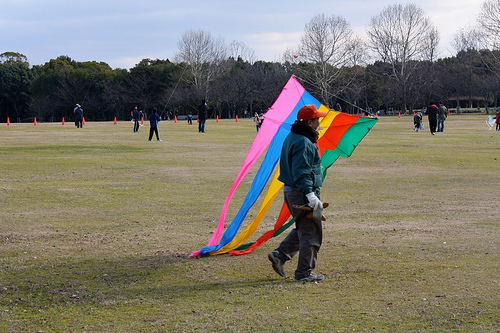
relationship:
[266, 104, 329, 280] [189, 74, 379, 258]
man with kite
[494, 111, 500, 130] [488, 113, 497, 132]
person with kite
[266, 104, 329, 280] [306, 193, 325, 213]
man with gloves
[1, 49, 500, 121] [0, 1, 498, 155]
trees in background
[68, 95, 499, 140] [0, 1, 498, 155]
people in background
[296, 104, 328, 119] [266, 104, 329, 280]
cap on man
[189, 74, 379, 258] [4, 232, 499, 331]
kite on ground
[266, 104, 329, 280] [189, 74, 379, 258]
man holding kite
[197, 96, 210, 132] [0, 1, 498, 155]
guy in background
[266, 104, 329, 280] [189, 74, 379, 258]
man carrying kite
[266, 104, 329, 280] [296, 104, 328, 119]
man wearing cap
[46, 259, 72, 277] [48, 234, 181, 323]
grass in patches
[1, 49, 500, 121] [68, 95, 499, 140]
trees behind people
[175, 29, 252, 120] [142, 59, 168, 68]
tree missing leaves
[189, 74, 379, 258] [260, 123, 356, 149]
kite has colors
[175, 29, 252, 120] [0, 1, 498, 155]
tree in background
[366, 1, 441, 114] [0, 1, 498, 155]
tree in background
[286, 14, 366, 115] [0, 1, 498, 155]
tree in background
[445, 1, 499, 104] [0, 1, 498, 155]
tree in background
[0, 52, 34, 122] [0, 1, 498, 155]
tree in background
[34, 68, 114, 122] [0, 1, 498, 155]
tree in background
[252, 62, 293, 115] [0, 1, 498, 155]
tree in background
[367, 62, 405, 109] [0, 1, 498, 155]
tree in background